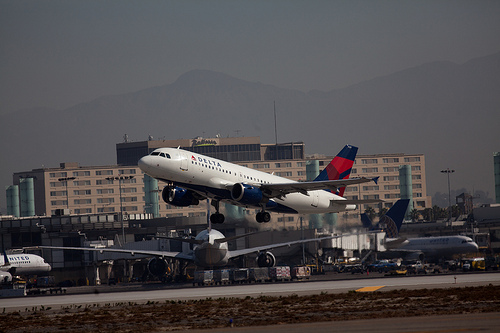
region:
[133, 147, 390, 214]
an aeoplane taking off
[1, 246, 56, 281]
a white plane parkked at the runway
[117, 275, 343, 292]
the tarmacked runway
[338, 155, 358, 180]
a red and blue coloured tail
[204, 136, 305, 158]
the control tower of the airport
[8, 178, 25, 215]
blue tanks beside the house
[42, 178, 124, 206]
a brown large house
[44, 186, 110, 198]
the brown house has windows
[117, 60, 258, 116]
the outline of a mountain at a distance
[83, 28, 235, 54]
the sky is dark and foggy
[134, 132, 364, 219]
white red and blue airplane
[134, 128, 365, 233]
delta brand airplane in sky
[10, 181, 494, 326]
runway at airport lined with planes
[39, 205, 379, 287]
large silver commercial airplane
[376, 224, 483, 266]
white Delta airplane parked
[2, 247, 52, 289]
white united plane parked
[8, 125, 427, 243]
large windowed building near airport with sign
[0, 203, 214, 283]
part of air terminal bulding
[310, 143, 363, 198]
red and blue wing tip of airplane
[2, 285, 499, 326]
patchy grass land surrounding airport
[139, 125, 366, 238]
the plane is delta airways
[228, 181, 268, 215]
the engine is blue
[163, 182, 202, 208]
the engine is blue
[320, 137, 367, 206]
the tail ie blue and red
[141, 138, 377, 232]
the plane is taking off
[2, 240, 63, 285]
the plane belongs to united airlines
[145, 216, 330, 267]
the plane is parked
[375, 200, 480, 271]
the plane is united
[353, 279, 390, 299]
the strip is yellow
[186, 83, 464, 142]
hills are in the background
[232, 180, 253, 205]
part of an engine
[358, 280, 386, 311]
part of a ground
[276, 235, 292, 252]
edge of a wing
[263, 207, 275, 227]
part fo a wheel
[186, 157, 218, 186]
;part of a plane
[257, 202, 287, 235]
part of a wheel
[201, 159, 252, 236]
part of a plane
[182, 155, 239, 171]
name of airlines on plane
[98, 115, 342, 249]
plane is taking off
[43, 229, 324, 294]
plane waiting to depart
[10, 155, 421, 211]
building in the background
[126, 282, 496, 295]
runway is gray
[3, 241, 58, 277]
plane from airlines is at gate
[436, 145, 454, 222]
lights to guide planes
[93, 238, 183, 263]
item to take passenger to planes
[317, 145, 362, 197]
tail of plane is red and blue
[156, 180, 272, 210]
engines are in blue